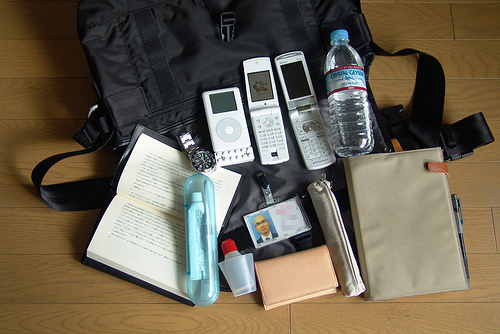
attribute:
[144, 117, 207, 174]
wristwatch — black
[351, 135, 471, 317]
dairy — beige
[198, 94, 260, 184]
ipod — white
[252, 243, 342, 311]
wallet — beige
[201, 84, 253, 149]
ipod — white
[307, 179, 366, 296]
pouch — long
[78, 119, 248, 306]
book — black, open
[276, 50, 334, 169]
cell phone — white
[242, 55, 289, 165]
cell phone — white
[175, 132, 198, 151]
strap — metal